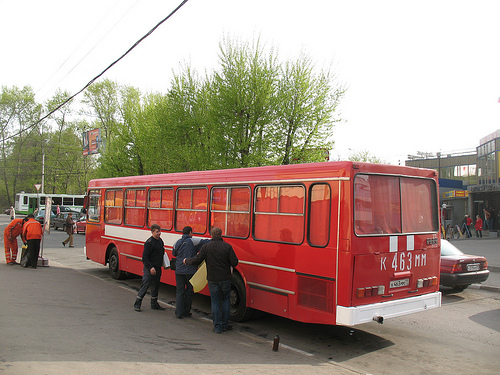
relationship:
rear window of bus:
[349, 170, 440, 236] [88, 170, 440, 307]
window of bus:
[87, 186, 105, 226] [84, 159, 441, 337]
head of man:
[149, 223, 164, 235] [133, 213, 164, 313]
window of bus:
[122, 187, 146, 227] [84, 159, 441, 337]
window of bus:
[245, 178, 307, 246] [84, 159, 441, 337]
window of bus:
[208, 191, 250, 231] [84, 159, 441, 337]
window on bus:
[251, 184, 307, 244] [84, 159, 441, 337]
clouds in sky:
[34, 33, 480, 92] [17, 0, 499, 154]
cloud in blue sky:
[156, 0, 493, 159] [0, 0, 498, 164]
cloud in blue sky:
[0, 0, 105, 137] [0, 0, 498, 164]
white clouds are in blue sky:
[173, 35, 207, 60] [0, 0, 498, 164]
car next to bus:
[435, 233, 495, 300] [84, 159, 441, 337]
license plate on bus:
[388, 277, 410, 288] [84, 159, 441, 337]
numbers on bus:
[387, 246, 425, 280] [84, 159, 441, 337]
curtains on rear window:
[353, 174, 436, 231] [349, 166, 446, 245]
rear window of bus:
[349, 166, 446, 245] [84, 159, 441, 337]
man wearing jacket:
[18, 209, 47, 262] [22, 220, 42, 240]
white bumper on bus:
[335, 290, 442, 325] [84, 159, 441, 337]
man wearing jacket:
[22, 213, 42, 269] [22, 218, 42, 243]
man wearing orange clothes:
[3, 213, 18, 262] [5, 217, 19, 255]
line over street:
[0, 0, 185, 142] [1, 210, 498, 373]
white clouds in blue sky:
[362, 67, 444, 137] [3, 0, 498, 164]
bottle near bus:
[272, 333, 280, 352] [84, 159, 441, 337]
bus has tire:
[84, 159, 441, 337] [104, 247, 120, 273]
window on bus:
[102, 183, 126, 226] [84, 159, 441, 337]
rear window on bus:
[349, 170, 440, 236] [84, 159, 441, 337]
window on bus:
[208, 191, 250, 231] [84, 159, 441, 337]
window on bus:
[174, 183, 206, 235] [84, 159, 441, 337]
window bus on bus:
[145, 188, 174, 230] [84, 159, 441, 337]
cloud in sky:
[380, 29, 410, 68] [3, 2, 498, 109]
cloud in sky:
[232, 7, 289, 48] [259, 10, 284, 28]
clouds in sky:
[35, 6, 97, 60] [8, 0, 498, 135]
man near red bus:
[181, 227, 241, 335] [75, 161, 445, 350]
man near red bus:
[169, 222, 209, 319] [75, 161, 445, 350]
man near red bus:
[132, 220, 169, 312] [75, 161, 445, 350]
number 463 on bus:
[384, 247, 417, 271] [53, 160, 448, 330]